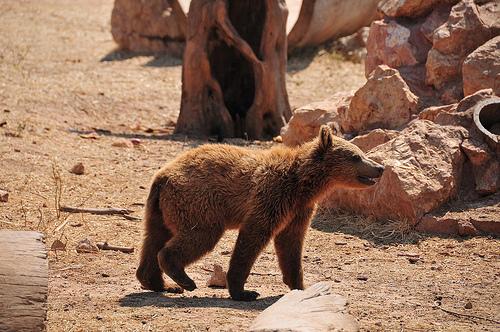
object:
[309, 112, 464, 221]
rock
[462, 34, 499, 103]
rock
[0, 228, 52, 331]
log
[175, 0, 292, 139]
stump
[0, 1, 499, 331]
cage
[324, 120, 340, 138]
ear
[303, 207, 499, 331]
grass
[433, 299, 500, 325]
sticks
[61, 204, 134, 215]
sticks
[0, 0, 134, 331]
grass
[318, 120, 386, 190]
head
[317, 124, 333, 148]
ear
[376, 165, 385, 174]
nose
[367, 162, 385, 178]
snout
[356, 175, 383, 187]
mouth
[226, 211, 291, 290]
front leg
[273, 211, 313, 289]
front leg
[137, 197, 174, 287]
back leg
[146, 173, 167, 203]
tail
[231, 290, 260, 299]
paw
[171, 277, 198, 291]
paw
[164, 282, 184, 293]
paw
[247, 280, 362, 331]
log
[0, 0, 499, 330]
floor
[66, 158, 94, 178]
rock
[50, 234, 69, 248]
rock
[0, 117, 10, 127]
rock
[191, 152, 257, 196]
fur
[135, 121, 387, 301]
bear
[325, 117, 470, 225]
rocks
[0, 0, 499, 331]
dirt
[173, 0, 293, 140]
treestump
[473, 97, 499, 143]
circularobject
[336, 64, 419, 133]
rock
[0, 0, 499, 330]
ground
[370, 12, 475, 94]
rock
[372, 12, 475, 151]
rock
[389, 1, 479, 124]
rock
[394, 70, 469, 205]
rock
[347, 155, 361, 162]
eye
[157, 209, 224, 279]
leg